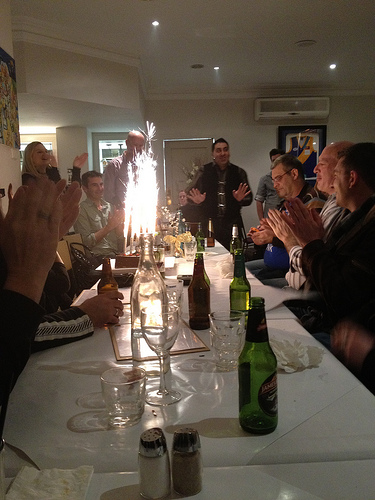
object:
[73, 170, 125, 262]
people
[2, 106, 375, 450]
party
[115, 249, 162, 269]
cake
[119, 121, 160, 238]
sparklers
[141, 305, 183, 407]
wine glass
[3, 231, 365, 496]
table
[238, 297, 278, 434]
glass bottle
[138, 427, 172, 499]
salt shaker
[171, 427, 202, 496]
pepper shaker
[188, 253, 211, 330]
glass bottle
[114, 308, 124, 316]
finger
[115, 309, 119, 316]
ring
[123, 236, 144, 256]
candles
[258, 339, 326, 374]
napkin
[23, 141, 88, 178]
woman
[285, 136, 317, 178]
jersey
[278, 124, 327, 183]
picture frame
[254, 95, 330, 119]
ac unit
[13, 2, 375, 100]
ceiling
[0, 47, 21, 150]
picture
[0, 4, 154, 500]
left hand side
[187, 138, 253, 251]
man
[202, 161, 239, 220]
vest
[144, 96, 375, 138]
wall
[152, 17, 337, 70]
lights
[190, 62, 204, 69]
speaker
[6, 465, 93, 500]
napkin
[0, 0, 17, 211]
wall